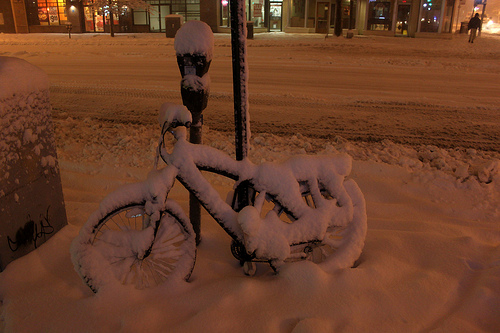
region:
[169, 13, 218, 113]
a metal parking meter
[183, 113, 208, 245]
a gray metal pole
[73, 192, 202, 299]
the wheel of a bicycle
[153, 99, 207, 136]
the handle bars of a bicycle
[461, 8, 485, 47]
a person on the street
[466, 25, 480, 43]
the legs of a person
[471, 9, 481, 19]
the head of a person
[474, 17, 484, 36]
the arm of a person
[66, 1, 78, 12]
a light on the building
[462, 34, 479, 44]
the shoes on the person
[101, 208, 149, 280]
part of a wheel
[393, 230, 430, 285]
part of a snow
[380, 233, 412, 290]
part of a snow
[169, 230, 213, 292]
part of a wheel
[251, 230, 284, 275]
part of a pedal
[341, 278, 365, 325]
part of a ground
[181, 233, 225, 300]
part of a wheel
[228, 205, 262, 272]
part of a metal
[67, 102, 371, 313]
The snow covered bike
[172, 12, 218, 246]
The meter behind the bike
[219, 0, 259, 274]
The tall pole next to parking meter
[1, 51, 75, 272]
The large grey box next to the bike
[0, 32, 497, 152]
The road behind the bike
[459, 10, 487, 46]
The person shown across the street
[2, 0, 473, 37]
The shops that are shown across the street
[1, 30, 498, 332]
The ground covered in snow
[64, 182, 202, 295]
The front wheel of the bike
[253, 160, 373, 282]
The back wheel of the bike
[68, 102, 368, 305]
A bicycle covered in snow.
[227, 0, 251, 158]
A black sign post covered in snow.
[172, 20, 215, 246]
A parking meter covered in snow.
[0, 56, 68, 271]
A concrete block covered in snow.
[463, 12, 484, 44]
A person wearing a black coat.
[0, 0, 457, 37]
A line of shops.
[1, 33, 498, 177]
The street is covered in slushy snow.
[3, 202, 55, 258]
Graffiti on the concrete block.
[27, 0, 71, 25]
A store front window.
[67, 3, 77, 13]
A light fixture.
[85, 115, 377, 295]
a bike in the snow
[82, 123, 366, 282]
snow on the bike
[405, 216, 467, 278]
the snow is white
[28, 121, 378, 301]
bike in the snow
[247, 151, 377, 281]
back tire of bike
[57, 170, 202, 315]
front tire of bike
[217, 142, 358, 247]
snow on the bike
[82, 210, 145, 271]
spokes on the bike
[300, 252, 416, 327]
snow next to bike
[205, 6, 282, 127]
pole next to bike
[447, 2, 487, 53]
person in the distance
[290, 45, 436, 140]
road with snow on it